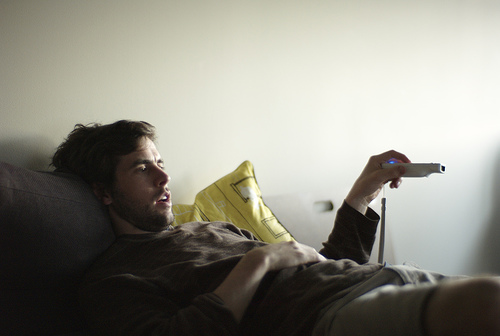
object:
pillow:
[165, 161, 294, 249]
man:
[45, 121, 499, 336]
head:
[48, 119, 174, 233]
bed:
[0, 161, 484, 331]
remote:
[383, 159, 448, 179]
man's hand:
[349, 151, 413, 201]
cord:
[376, 188, 390, 264]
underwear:
[314, 260, 440, 332]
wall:
[2, 4, 239, 179]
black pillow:
[3, 162, 113, 324]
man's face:
[116, 133, 172, 230]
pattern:
[229, 172, 257, 202]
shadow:
[3, 130, 57, 166]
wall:
[0, 0, 500, 277]